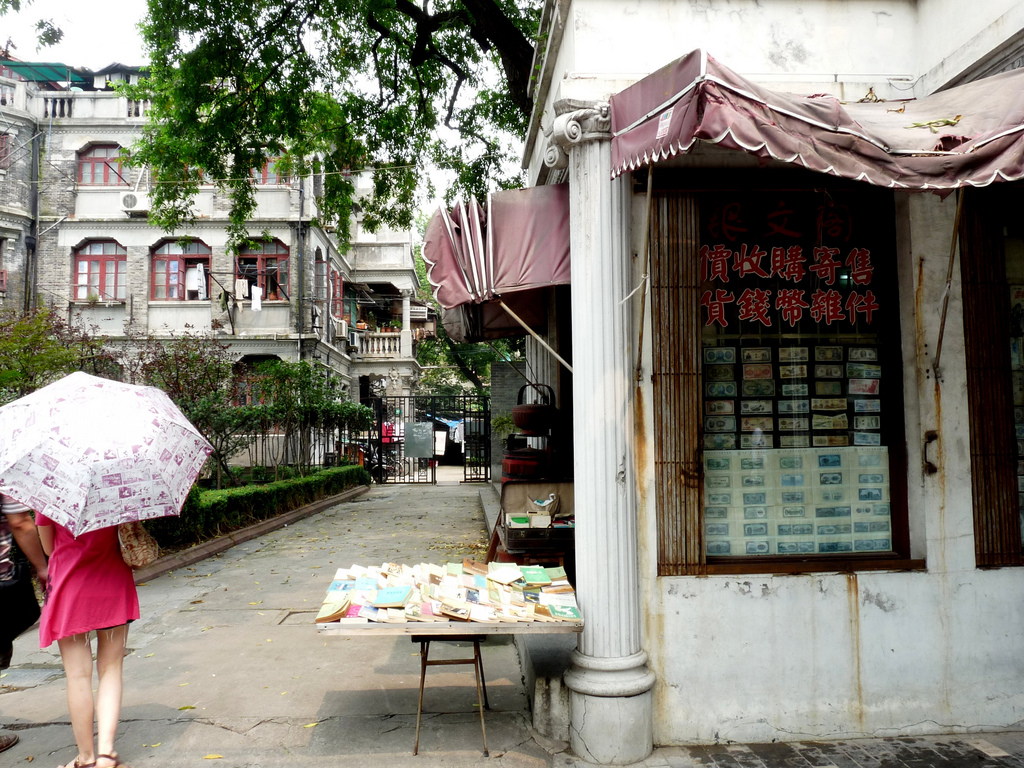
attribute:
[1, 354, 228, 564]
umbrella — pink, open white 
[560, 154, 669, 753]
column — white stone 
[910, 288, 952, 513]
stain — rust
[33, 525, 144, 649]
sundress — bright pink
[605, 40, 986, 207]
awning — old, damaged, red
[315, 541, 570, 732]
table — display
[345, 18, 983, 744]
store — entrance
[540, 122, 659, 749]
pillar — decorative 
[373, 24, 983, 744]
building — corner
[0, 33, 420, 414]
building — side 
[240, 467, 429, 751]
sidewalk — gray slate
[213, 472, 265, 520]
hedge — trimmed green 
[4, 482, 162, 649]
dress — PINK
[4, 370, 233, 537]
umbrella — WHITE, PINK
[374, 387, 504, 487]
gate — BLACK, IRON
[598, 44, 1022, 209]
awning — WINE COLORED, RED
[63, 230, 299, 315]
windows — THREE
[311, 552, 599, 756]
table — LARGE, MAKESHIFT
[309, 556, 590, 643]
books — MANY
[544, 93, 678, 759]
column — LONG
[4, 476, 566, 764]
walkway — CRACKED, CONCRETE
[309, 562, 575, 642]
papers — WHITE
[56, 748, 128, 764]
sandals — PINK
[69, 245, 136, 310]
window frames — RED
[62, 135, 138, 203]
window frames — RED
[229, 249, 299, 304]
window frames — RED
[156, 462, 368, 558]
hedges — trimmed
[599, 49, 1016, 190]
window awning — purple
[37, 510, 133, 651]
dress — cherry colored, short